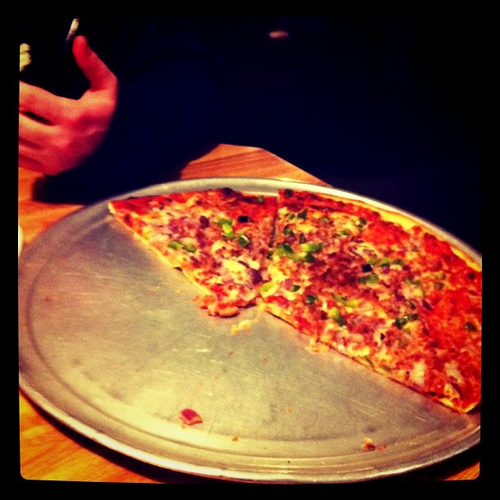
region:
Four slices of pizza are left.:
[106, 185, 483, 417]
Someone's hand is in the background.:
[17, 33, 117, 175]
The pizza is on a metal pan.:
[18, 175, 481, 485]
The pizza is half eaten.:
[109, 188, 482, 412]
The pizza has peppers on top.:
[108, 188, 480, 411]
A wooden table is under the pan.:
[16, 143, 481, 480]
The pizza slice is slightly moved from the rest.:
[107, 193, 279, 314]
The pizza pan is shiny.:
[18, 176, 482, 482]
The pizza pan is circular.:
[18, 175, 480, 482]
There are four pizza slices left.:
[109, 187, 481, 412]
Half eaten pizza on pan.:
[18, 178, 483, 484]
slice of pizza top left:
[102, 175, 294, 323]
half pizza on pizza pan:
[105, 168, 486, 416]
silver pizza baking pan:
[16, 168, 496, 499]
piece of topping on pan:
[173, 398, 204, 430]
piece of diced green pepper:
[212, 216, 238, 241]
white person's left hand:
[20, 33, 130, 188]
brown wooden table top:
[17, 109, 482, 481]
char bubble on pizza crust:
[217, 182, 270, 208]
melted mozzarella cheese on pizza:
[219, 256, 251, 276]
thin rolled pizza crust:
[106, 181, 283, 219]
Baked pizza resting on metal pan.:
[17, 176, 478, 481]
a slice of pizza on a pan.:
[97, 191, 274, 325]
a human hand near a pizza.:
[21, 35, 138, 189]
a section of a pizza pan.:
[92, 331, 207, 388]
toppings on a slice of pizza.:
[117, 168, 288, 330]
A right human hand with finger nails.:
[16, 35, 136, 208]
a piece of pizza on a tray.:
[174, 403, 211, 438]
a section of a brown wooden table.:
[190, 132, 334, 190]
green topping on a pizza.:
[214, 213, 240, 248]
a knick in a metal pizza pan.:
[186, 334, 223, 361]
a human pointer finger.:
[20, 71, 68, 125]